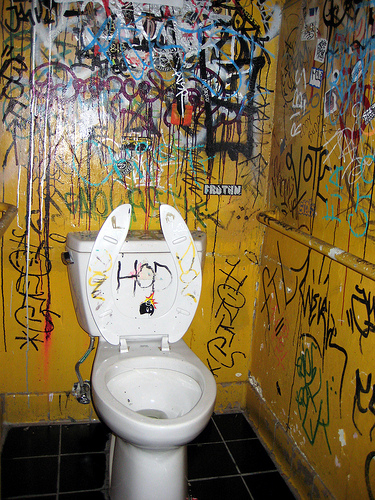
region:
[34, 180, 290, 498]
the toilet is white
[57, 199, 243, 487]
the toilet has graffiti on it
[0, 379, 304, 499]
the floor is black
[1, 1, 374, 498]
the walls are yellow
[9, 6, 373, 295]
the wall has graffiti on them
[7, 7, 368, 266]
the graffiti is multicolored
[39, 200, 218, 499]
the toilet is dirty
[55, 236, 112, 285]
the toilet has a silver handle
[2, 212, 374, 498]
the walls are dirty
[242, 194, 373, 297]
the rail beside the toilet is yellow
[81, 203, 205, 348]
a painted toilet seat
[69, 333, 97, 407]
a silver pipe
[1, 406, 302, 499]
a black tiled floor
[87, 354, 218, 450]
a toilet bowl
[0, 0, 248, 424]
a yellow wall covered in graffiti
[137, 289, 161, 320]
a black bomb sticker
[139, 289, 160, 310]
a yellow and red fuse on the sticker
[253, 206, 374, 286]
a painted yellow pipe on the wall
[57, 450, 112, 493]
a black tile on the floor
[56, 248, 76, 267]
a metal toilet handle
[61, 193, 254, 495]
the toilet is open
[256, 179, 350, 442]
the wall is yellow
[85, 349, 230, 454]
the toilet is shallow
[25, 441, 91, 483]
the tiles are black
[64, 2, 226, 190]
there's graffiti on the wall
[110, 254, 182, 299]
The toilet says HOD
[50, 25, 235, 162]
the wall is dirty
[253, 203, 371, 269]
the pipe is yellow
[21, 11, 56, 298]
the paint is runny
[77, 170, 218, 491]
white toilet with graffiti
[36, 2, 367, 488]
bathroom with lots of graffiti on walls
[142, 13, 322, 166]
graffiti on yellow walls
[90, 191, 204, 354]
white toilet seat in the up position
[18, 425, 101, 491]
black tile bathroom floor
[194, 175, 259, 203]
black sticker with white lettering on wall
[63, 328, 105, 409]
silver toilet plumbing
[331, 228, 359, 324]
long red drip of paint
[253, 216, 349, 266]
yellow hand rail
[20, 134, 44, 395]
long white drip of paint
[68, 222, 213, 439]
One toilet is seen.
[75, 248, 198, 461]
Toilet is white color.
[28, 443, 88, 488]
Floor is black color.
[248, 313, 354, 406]
Wall is yellow color.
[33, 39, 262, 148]
Letters are scribbled in wall.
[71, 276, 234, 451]
Toilet seat is open.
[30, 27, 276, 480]
Picture is taken in bathroom.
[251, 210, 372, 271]
Pipeline is in wall.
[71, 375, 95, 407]
Control is silver color.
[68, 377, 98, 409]
control is attached to wall.